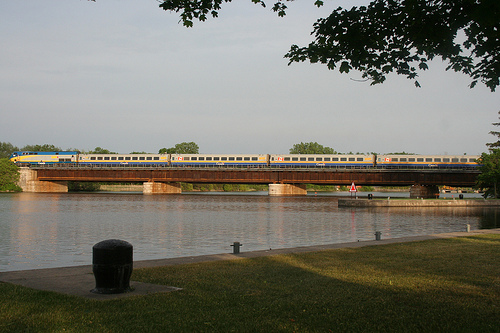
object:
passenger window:
[184, 157, 189, 160]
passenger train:
[9, 151, 482, 170]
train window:
[104, 157, 109, 160]